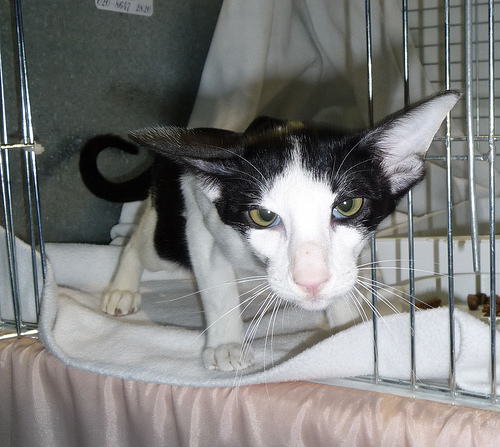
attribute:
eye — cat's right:
[241, 197, 283, 231]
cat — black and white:
[79, 88, 487, 373]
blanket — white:
[28, 220, 497, 419]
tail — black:
[69, 127, 156, 202]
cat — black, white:
[112, 77, 456, 345]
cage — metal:
[2, 2, 498, 396]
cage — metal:
[3, 25, 62, 324]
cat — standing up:
[76, 96, 473, 362]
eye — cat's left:
[342, 191, 370, 223]